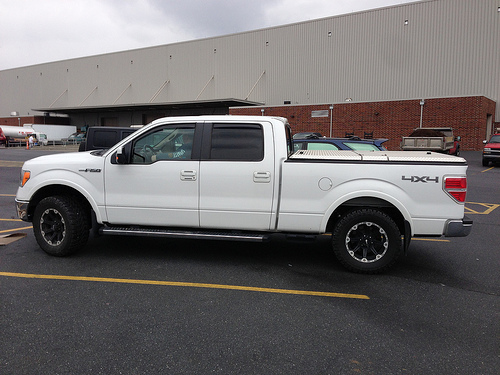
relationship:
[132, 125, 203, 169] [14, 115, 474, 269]
person sitting in car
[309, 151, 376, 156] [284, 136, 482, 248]
bed cover on bed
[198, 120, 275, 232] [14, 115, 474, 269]
doors on car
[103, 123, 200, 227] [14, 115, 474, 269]
door on car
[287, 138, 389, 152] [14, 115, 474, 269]
car next to car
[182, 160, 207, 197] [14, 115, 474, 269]
doorhandle on car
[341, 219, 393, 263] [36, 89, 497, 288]
rim on truck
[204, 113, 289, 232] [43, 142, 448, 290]
cab on back of truck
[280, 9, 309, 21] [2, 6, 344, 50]
gray cloud in sky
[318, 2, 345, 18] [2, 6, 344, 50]
gray cloud in sky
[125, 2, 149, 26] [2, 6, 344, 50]
gray cloud in sky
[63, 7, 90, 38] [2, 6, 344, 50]
gray cloud in sky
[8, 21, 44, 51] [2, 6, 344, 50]
gray cloud in sky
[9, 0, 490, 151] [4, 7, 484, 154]
wall of building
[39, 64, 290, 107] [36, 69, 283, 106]
row of poles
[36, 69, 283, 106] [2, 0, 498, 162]
poles on building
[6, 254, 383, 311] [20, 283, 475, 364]
line on asphalt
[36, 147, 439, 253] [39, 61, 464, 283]
side of truck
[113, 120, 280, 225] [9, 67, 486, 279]
doors on truck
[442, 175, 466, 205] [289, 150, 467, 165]
light on bed